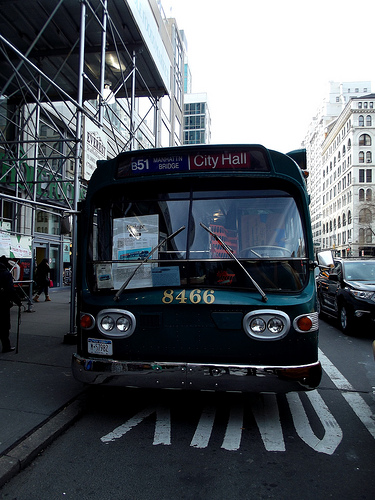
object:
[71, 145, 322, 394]
bus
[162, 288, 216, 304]
numbers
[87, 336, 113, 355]
plate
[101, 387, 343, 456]
letters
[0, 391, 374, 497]
road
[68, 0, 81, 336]
pole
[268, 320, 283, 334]
headlight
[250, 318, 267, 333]
headlight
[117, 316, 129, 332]
headlight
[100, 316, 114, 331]
headlight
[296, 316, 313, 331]
headlight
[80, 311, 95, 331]
headlight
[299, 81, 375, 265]
building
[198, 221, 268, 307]
wiper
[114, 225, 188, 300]
wiper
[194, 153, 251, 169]
sign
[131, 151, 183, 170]
sign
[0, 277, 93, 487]
sidewalk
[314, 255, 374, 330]
car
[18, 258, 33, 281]
sign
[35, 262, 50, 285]
coat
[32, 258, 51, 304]
woman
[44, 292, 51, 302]
boots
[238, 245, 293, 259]
wheel